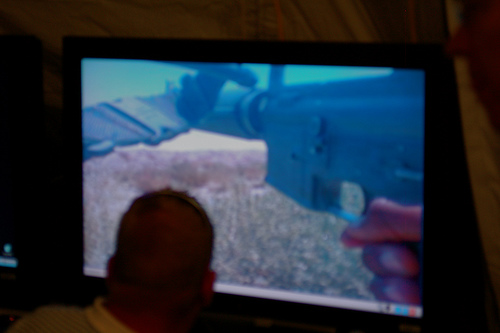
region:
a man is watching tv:
[9, 174, 256, 329]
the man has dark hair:
[102, 184, 221, 324]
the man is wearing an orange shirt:
[3, 302, 132, 332]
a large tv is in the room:
[7, 27, 461, 332]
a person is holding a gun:
[168, 64, 423, 318]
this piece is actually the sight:
[268, 62, 288, 85]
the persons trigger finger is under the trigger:
[336, 199, 423, 302]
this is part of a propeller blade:
[84, 86, 202, 166]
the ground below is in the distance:
[83, 147, 410, 307]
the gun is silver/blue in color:
[261, 81, 413, 227]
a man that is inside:
[11, 137, 303, 332]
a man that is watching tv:
[29, 112, 309, 329]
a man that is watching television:
[37, 40, 454, 332]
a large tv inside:
[37, 18, 466, 331]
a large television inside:
[54, 16, 475, 325]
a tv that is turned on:
[60, 18, 475, 325]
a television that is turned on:
[47, 7, 493, 321]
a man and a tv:
[57, 27, 479, 332]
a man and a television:
[14, 15, 499, 315]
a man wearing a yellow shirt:
[32, 166, 286, 331]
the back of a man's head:
[87, 183, 222, 332]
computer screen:
[75, 52, 427, 320]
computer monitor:
[54, 28, 458, 332]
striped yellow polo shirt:
[7, 298, 141, 331]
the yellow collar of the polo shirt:
[81, 297, 133, 332]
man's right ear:
[199, 267, 219, 304]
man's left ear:
[102, 253, 121, 288]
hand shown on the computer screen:
[339, 193, 426, 313]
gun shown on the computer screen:
[161, 68, 428, 233]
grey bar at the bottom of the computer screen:
[81, 260, 423, 320]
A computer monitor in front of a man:
[68, 59, 423, 319]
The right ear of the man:
[204, 268, 218, 296]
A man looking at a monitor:
[16, 191, 219, 329]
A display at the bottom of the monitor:
[378, 302, 420, 317]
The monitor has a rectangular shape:
[72, 67, 430, 280]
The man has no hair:
[101, 175, 206, 318]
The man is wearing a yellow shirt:
[16, 292, 135, 331]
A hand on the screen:
[352, 198, 419, 303]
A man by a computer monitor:
[1, 183, 215, 328]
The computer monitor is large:
[81, 42, 430, 323]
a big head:
[95, 183, 222, 319]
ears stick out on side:
[102, 253, 217, 301]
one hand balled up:
[339, 196, 423, 303]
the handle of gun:
[341, 185, 424, 302]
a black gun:
[80, 57, 424, 296]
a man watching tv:
[11, 27, 498, 331]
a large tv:
[56, 30, 498, 330]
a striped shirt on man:
[8, 293, 142, 332]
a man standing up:
[439, 0, 498, 140]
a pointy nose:
[440, 25, 471, 64]